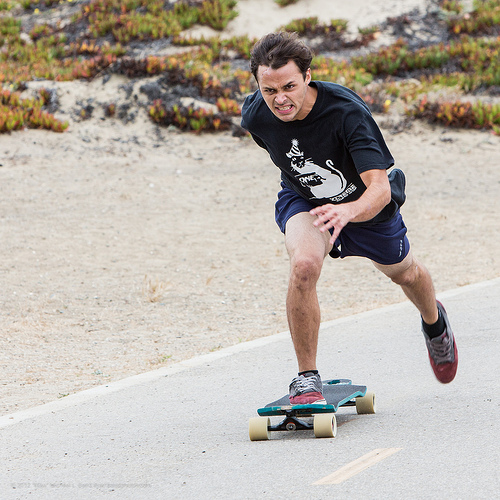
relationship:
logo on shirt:
[277, 132, 359, 206] [237, 97, 405, 219]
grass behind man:
[1, 3, 500, 149] [219, 24, 461, 469]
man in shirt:
[219, 24, 461, 469] [237, 97, 405, 219]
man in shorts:
[219, 24, 461, 469] [261, 186, 421, 281]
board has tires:
[241, 371, 386, 445] [262, 393, 374, 441]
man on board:
[219, 24, 461, 469] [241, 371, 386, 445]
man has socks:
[219, 24, 461, 469] [289, 310, 457, 376]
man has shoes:
[219, 24, 461, 469] [279, 317, 474, 407]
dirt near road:
[15, 141, 499, 327] [0, 282, 499, 493]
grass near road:
[1, 3, 500, 149] [0, 282, 499, 493]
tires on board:
[262, 393, 374, 441] [241, 371, 386, 445]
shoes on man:
[279, 317, 474, 407] [219, 24, 461, 469]